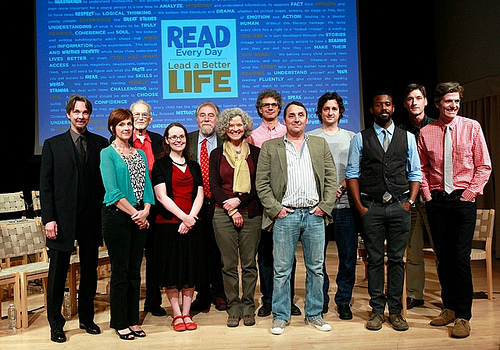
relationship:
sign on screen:
[161, 18, 237, 97] [32, 1, 366, 156]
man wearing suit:
[39, 94, 110, 342] [39, 130, 109, 326]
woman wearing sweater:
[99, 108, 156, 341] [101, 143, 157, 208]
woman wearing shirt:
[150, 121, 212, 331] [152, 154, 205, 218]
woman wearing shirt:
[150, 121, 212, 331] [157, 160, 193, 223]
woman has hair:
[208, 107, 265, 327] [214, 106, 253, 139]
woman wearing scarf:
[208, 107, 265, 327] [221, 138, 254, 197]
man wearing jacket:
[253, 101, 339, 336] [254, 134, 339, 228]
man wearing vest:
[344, 91, 424, 332] [359, 126, 410, 201]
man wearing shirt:
[416, 80, 492, 339] [416, 116, 493, 201]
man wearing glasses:
[250, 89, 301, 318] [262, 102, 276, 109]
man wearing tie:
[187, 100, 229, 313] [199, 138, 212, 200]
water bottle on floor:
[7, 302, 20, 334] [2, 237, 497, 349]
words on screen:
[45, 0, 163, 93] [32, 1, 366, 156]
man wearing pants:
[39, 94, 110, 342] [46, 247, 99, 328]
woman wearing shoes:
[150, 121, 212, 331] [171, 313, 199, 333]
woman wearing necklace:
[150, 121, 212, 331] [171, 157, 188, 167]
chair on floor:
[420, 206, 496, 300] [2, 237, 497, 349]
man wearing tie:
[416, 80, 492, 339] [441, 126, 455, 194]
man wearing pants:
[416, 80, 492, 339] [424, 190, 476, 320]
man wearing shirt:
[344, 91, 424, 332] [345, 123, 423, 186]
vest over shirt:
[359, 126, 410, 201] [345, 123, 423, 186]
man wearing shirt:
[250, 89, 301, 318] [248, 120, 288, 147]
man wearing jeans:
[253, 101, 339, 336] [270, 208, 328, 318]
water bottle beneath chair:
[7, 302, 20, 334] [0, 223, 22, 332]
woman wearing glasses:
[150, 121, 212, 331] [167, 134, 189, 142]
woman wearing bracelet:
[208, 107, 265, 327] [229, 207, 239, 217]